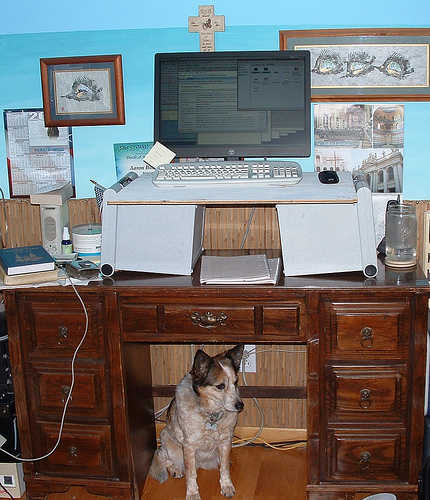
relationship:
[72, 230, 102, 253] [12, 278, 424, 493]
discs on desk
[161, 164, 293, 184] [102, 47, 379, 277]
keyboard of computer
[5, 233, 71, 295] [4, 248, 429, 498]
book on desk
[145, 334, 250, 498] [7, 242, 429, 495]
dog under table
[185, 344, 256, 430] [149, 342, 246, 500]
head of dog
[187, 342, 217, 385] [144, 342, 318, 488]
ear of dog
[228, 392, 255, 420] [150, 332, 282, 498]
nose of dog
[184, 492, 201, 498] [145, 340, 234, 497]
foot of dog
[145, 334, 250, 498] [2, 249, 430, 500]
dog under desk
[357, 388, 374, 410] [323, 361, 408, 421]
handle on drawer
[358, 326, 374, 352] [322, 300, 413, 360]
handle on drawer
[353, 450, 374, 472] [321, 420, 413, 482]
handle on drawer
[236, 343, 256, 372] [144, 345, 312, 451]
plug in background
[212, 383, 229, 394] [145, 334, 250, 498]
eye of dog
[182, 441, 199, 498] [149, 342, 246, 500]
leg of dog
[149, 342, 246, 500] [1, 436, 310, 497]
dog down on floor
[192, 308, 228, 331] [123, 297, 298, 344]
handle on drawer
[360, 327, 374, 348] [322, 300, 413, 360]
handle on drawer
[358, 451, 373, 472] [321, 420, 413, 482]
handle on drawer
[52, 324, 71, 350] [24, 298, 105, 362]
handle on drawer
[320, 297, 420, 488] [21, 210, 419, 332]
drawers on table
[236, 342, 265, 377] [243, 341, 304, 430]
outlet on wall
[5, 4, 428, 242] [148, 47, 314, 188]
wall behind computer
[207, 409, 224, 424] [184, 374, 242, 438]
tag on neck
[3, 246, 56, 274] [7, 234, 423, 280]
book on surface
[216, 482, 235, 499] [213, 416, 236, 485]
claw on leg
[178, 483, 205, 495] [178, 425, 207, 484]
claw on leg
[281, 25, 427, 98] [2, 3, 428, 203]
picture on wall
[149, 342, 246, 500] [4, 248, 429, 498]
dog sitting under desk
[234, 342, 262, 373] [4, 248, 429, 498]
electrical outlet under desk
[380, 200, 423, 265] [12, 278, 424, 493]
jar on desk